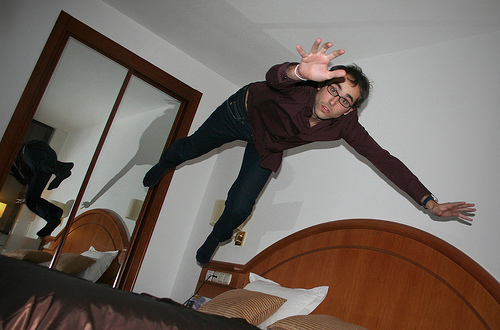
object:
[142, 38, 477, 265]
man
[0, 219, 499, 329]
bed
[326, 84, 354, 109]
glasses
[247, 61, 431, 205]
shirt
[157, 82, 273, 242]
jeans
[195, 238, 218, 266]
socks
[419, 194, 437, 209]
watch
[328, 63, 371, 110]
hair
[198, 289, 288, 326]
pillow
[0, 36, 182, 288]
mirror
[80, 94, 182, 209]
shadow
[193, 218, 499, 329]
headboard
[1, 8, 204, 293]
closet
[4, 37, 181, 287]
mirrored doors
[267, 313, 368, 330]
pillows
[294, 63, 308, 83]
bracelet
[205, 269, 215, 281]
plugs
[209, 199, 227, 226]
lamp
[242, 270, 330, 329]
pillow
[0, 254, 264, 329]
comforter